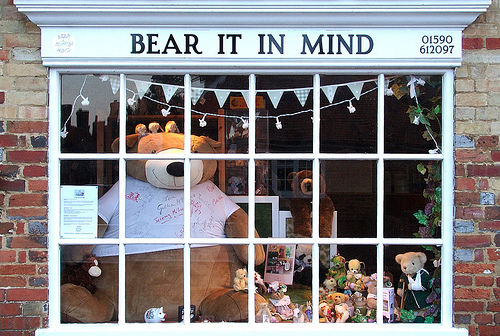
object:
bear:
[65, 121, 266, 324]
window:
[11, 0, 491, 336]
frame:
[44, 67, 456, 324]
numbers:
[420, 35, 455, 54]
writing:
[125, 182, 224, 239]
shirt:
[91, 174, 241, 258]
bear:
[233, 268, 248, 291]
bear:
[267, 280, 295, 322]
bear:
[344, 258, 366, 291]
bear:
[321, 292, 349, 323]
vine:
[382, 75, 440, 324]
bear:
[287, 170, 336, 238]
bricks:
[0, 0, 500, 336]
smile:
[152, 169, 201, 187]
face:
[126, 132, 218, 191]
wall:
[453, 72, 500, 163]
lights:
[60, 74, 442, 154]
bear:
[395, 251, 435, 323]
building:
[0, 0, 500, 336]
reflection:
[60, 71, 172, 152]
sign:
[39, 28, 463, 60]